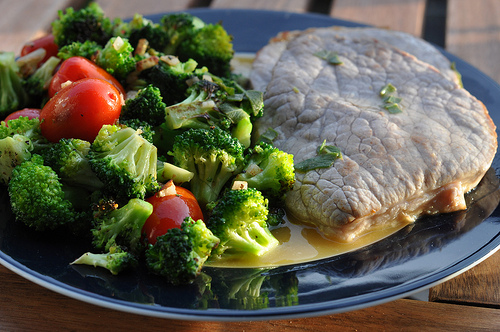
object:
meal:
[0, 1, 498, 285]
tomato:
[39, 77, 126, 141]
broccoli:
[120, 81, 170, 127]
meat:
[252, 23, 497, 242]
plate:
[1, 9, 499, 321]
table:
[1, 0, 499, 330]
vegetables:
[163, 75, 244, 133]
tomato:
[137, 183, 204, 244]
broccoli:
[86, 122, 162, 202]